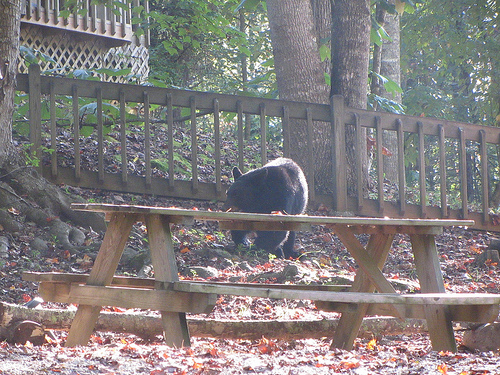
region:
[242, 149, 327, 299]
This is a brown bear that is in the park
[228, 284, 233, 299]
There is a light wood color of the picnic table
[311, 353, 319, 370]
There are red leaves on the ground in this photo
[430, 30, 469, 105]
There are green leaves on the tree here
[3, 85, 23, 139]
The trunk of this tree is a light brown color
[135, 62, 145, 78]
There is a white color on this temporary fencing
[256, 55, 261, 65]
The sky looks to be a very bright white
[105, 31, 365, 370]
This photo was taken in the state of Wisconsin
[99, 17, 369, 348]
This photo was taken in the town of Tomahawk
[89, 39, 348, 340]
This photo was taken in the season of Autumn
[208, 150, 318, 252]
black bear on a bench.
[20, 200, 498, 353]
a brown wooden bench.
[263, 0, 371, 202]
tree trunk behind a fence.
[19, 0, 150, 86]
a tall wooden fence.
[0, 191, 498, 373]
leaf covered ground.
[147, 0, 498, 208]
A forest filled with leafy green trees.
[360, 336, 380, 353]
a brown leaf laying on the ground.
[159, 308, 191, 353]
a wooden post on a bench.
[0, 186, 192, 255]
tree roots sticking out of the ground.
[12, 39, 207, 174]
green plants growing on the side of a hill.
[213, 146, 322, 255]
bar walking on the ground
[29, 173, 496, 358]
wooden picnic table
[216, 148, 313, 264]
black bear on all fours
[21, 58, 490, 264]
wooden fence behind black bear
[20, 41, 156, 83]
wooden lattice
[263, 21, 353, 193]
tree trunk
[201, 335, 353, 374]
colored leaves on the ground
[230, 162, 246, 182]
bear's right ear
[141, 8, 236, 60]
many green leaves on tree branches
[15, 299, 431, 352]
tree laying on the ground near colored leaves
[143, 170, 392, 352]
An empty picnic table.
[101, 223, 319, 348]
An empty picnic table.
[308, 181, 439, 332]
An empty picnic table.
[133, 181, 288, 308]
An empty picnic table.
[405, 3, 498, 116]
many green leaves hanging from the tree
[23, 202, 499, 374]
lots of brown leaves under a brown picnic table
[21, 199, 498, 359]
wooden picnic table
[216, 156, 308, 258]
brown bear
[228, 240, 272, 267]
green plants in the ground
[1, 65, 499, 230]
a long wooden fence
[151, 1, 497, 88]
lots of trees and green leaves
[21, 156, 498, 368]
brown bear behind a wooden bench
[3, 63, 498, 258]
brown bear beneath long wooden fence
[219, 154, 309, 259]
dark colored bear